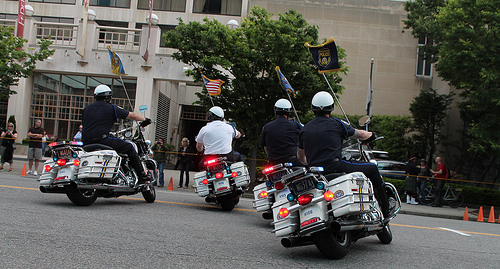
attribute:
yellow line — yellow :
[0, 184, 498, 237]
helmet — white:
[273, 91, 300, 118]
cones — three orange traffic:
[459, 203, 498, 225]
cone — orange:
[487, 204, 496, 221]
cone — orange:
[475, 205, 485, 220]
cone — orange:
[462, 205, 469, 219]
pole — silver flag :
[189, 58, 210, 96]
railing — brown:
[32, 19, 82, 47]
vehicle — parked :
[341, 146, 409, 179]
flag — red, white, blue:
[145, 41, 247, 117]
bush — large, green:
[165, 6, 352, 121]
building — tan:
[4, 1, 444, 177]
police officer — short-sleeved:
[305, 105, 405, 208]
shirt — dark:
[298, 112, 355, 162]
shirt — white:
[185, 107, 246, 170]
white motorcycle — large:
[25, 112, 167, 207]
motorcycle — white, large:
[244, 152, 441, 255]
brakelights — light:
[200, 173, 243, 180]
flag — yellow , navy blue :
[299, 38, 345, 85]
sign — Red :
[13, 8, 33, 34]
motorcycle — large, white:
[251, 157, 311, 225]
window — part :
[412, 30, 433, 80]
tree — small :
[402, 85, 458, 175]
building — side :
[0, 0, 497, 183]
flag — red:
[11, 0, 36, 40]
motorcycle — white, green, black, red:
[30, 142, 150, 201]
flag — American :
[199, 67, 228, 102]